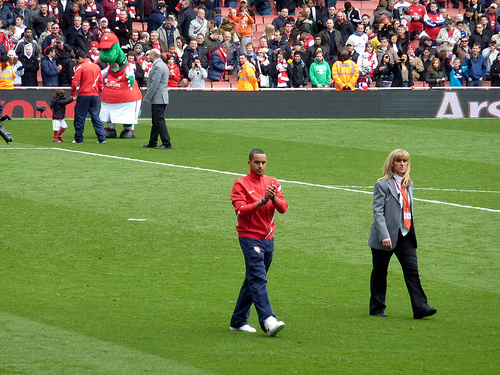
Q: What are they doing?
A: Walking.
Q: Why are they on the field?
A: Event staff.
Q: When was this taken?
A: During a game.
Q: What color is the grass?
A: Green.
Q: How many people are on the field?
A: 6.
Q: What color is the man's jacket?
A: Red.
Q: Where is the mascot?
A: The back of the field.